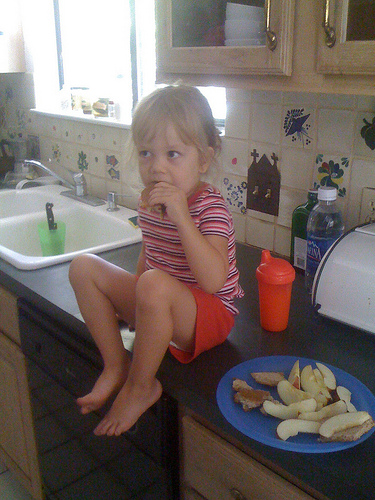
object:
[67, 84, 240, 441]
girl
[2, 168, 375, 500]
counter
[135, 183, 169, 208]
cookie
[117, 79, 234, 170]
hair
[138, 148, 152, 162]
eye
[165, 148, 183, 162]
eye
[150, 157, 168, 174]
nose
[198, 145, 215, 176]
ear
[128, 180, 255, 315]
shirt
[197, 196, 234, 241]
sleeve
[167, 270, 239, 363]
shorts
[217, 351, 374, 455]
plate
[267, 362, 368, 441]
apple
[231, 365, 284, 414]
bread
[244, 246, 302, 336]
cup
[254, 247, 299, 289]
lid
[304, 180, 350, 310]
bottle